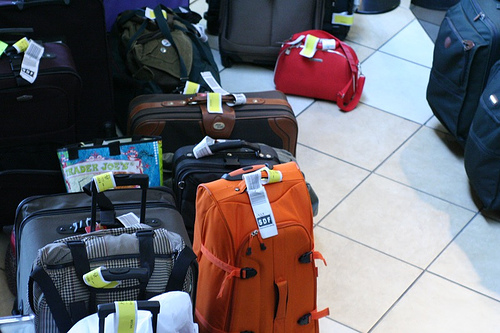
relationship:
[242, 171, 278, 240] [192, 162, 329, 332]
tag on luggage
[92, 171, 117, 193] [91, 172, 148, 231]
tag on luggage handle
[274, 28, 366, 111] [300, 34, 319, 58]
bag has a tag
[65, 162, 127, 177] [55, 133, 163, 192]
trader joe's on bag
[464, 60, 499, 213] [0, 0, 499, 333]
luggage on floor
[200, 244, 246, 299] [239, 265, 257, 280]
strap with a buckle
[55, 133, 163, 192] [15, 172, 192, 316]
bag next to luggage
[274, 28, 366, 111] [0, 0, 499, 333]
bag on floor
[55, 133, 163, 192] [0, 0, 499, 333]
bag on floor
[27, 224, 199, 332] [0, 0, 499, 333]
bag on floor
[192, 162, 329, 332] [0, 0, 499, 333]
luggage on floor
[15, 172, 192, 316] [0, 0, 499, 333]
luggage on floor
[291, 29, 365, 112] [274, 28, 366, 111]
strap on bag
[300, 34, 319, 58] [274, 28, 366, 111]
tag on bag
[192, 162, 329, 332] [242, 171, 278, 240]
luggage has a tag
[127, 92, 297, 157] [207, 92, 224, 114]
luggage has a tag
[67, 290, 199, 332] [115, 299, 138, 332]
luggage has a tag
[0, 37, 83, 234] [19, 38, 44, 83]
luggage has a tag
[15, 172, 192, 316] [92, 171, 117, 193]
luggage has a tag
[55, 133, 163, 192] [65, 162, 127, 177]
bag from trader joe's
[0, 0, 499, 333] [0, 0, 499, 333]
floor has lines